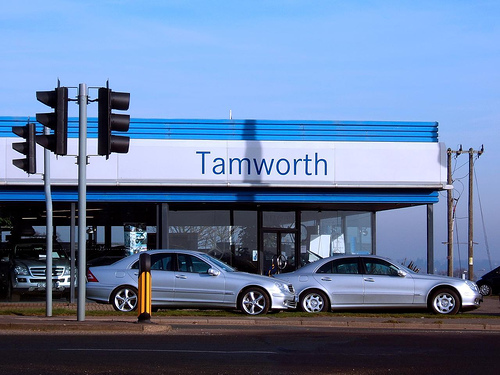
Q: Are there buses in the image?
A: No, there are no buses.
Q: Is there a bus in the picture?
A: No, there are no buses.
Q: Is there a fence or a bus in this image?
A: No, there are no buses or fences.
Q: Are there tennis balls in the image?
A: No, there are no tennis balls.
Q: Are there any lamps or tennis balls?
A: No, there are no tennis balls or lamps.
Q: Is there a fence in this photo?
A: No, there are no fences.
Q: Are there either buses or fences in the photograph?
A: No, there are no fences or buses.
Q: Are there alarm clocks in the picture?
A: No, there are no alarm clocks.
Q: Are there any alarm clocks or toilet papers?
A: No, there are no alarm clocks or toilet papers.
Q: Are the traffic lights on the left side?
A: Yes, the traffic lights are on the left of the image.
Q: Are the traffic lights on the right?
A: No, the traffic lights are on the left of the image.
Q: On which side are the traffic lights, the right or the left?
A: The traffic lights are on the left of the image.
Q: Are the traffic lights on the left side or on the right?
A: The traffic lights are on the left of the image.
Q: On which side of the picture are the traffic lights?
A: The traffic lights are on the left of the image.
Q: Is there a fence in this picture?
A: No, there are no fences.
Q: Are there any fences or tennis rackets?
A: No, there are no fences or tennis rackets.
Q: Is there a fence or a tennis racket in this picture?
A: No, there are no fences or rackets.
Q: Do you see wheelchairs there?
A: No, there are no wheelchairs.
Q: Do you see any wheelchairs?
A: No, there are no wheelchairs.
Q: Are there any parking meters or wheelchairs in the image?
A: No, there are no wheelchairs or parking meters.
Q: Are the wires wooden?
A: Yes, the wires are wooden.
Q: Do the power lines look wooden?
A: Yes, the power lines are wooden.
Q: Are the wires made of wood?
A: Yes, the wires are made of wood.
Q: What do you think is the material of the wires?
A: The wires are made of wood.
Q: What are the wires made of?
A: The wires are made of wood.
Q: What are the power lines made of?
A: The wires are made of wood.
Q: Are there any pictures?
A: No, there are no pictures.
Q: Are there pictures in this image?
A: No, there are no pictures.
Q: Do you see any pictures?
A: No, there are no pictures.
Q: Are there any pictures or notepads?
A: No, there are no pictures or notepads.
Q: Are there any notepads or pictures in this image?
A: No, there are no pictures or notepads.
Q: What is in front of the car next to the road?
A: The street lights are in front of the car.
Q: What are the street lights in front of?
A: The street lights are in front of the car.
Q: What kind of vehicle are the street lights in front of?
A: The street lights are in front of the car.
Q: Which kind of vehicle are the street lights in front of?
A: The street lights are in front of the car.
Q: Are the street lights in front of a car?
A: Yes, the street lights are in front of a car.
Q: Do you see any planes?
A: No, there are no planes.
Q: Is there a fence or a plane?
A: No, there are no airplanes or fences.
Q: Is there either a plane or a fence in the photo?
A: No, there are no airplanes or fences.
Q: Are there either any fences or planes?
A: No, there are no planes or fences.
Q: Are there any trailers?
A: No, there are no trailers.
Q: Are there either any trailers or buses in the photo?
A: No, there are no trailers or buses.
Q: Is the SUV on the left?
A: Yes, the SUV is on the left of the image.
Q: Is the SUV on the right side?
A: No, the SUV is on the left of the image.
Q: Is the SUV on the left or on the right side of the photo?
A: The SUV is on the left of the image.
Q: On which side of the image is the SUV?
A: The SUV is on the left of the image.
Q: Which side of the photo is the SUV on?
A: The SUV is on the left of the image.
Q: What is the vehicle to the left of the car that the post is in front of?
A: The vehicle is a SUV.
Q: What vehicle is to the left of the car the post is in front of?
A: The vehicle is a SUV.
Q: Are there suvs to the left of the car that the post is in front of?
A: Yes, there is a SUV to the left of the car.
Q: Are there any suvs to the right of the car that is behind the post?
A: No, the SUV is to the left of the car.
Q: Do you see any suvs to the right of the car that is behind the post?
A: No, the SUV is to the left of the car.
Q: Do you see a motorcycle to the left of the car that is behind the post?
A: No, there is a SUV to the left of the car.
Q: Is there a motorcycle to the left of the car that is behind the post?
A: No, there is a SUV to the left of the car.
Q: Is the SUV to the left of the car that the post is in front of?
A: Yes, the SUV is to the left of the car.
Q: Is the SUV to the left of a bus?
A: No, the SUV is to the left of the car.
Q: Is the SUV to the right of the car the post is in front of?
A: No, the SUV is to the left of the car.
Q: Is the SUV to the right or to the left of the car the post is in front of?
A: The SUV is to the left of the car.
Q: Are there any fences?
A: No, there are no fences.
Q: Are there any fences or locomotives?
A: No, there are no fences or locomotives.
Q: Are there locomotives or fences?
A: No, there are no fences or locomotives.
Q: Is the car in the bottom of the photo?
A: Yes, the car is in the bottom of the image.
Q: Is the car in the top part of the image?
A: No, the car is in the bottom of the image.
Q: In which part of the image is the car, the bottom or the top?
A: The car is in the bottom of the image.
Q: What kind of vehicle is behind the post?
A: The vehicle is a car.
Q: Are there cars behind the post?
A: Yes, there is a car behind the post.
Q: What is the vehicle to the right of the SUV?
A: The vehicle is a car.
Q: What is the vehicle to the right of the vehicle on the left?
A: The vehicle is a car.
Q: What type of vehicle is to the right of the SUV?
A: The vehicle is a car.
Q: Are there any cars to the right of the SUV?
A: Yes, there is a car to the right of the SUV.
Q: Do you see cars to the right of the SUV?
A: Yes, there is a car to the right of the SUV.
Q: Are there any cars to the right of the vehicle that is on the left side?
A: Yes, there is a car to the right of the SUV.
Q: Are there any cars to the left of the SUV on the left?
A: No, the car is to the right of the SUV.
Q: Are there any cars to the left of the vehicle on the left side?
A: No, the car is to the right of the SUV.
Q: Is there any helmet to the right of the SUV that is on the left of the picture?
A: No, there is a car to the right of the SUV.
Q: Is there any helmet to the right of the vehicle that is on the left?
A: No, there is a car to the right of the SUV.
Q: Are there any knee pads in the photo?
A: No, there are no knee pads.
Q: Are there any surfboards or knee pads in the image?
A: No, there are no knee pads or surfboards.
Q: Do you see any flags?
A: No, there are no flags.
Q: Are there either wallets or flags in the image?
A: No, there are no flags or wallets.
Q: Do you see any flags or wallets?
A: No, there are no flags or wallets.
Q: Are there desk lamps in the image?
A: No, there are no desk lamps.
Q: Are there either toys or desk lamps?
A: No, there are no desk lamps or toys.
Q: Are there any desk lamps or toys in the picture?
A: No, there are no desk lamps or toys.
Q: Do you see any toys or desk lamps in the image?
A: No, there are no desk lamps or toys.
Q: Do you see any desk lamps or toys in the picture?
A: No, there are no desk lamps or toys.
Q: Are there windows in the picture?
A: Yes, there is a window.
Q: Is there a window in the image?
A: Yes, there is a window.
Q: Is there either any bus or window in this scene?
A: Yes, there is a window.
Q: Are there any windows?
A: Yes, there is a window.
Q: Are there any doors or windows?
A: Yes, there is a window.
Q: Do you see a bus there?
A: No, there are no buses.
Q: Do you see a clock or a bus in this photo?
A: No, there are no buses or clocks.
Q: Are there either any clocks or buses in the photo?
A: No, there are no buses or clocks.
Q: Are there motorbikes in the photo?
A: No, there are no motorbikes.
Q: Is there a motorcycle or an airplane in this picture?
A: No, there are no motorcycles or airplanes.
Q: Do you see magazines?
A: No, there are no magazines.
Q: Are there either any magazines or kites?
A: No, there are no magazines or kites.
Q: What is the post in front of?
A: The post is in front of the car.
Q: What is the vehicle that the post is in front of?
A: The vehicle is a car.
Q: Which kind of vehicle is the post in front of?
A: The post is in front of the car.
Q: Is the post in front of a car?
A: Yes, the post is in front of a car.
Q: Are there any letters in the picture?
A: Yes, there are letters.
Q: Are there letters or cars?
A: Yes, there are letters.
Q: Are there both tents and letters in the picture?
A: No, there are letters but no tents.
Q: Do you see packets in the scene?
A: No, there are no packets.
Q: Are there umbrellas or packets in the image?
A: No, there are no packets or umbrellas.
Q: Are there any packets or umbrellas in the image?
A: No, there are no packets or umbrellas.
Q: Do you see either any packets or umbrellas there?
A: No, there are no packets or umbrellas.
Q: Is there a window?
A: Yes, there is a window.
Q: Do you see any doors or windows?
A: Yes, there is a window.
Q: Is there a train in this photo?
A: No, there are no trains.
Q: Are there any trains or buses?
A: No, there are no trains or buses.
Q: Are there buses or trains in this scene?
A: No, there are no trains or buses.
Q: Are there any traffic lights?
A: Yes, there is a traffic light.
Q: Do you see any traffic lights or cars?
A: Yes, there is a traffic light.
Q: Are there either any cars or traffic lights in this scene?
A: Yes, there is a traffic light.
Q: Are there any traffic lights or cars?
A: Yes, there is a traffic light.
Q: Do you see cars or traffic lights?
A: Yes, there is a traffic light.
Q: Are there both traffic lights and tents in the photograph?
A: No, there is a traffic light but no tents.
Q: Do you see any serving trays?
A: No, there are no serving trays.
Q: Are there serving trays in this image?
A: No, there are no serving trays.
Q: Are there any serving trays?
A: No, there are no serving trays.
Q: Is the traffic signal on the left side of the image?
A: Yes, the traffic signal is on the left of the image.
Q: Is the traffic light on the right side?
A: No, the traffic light is on the left of the image.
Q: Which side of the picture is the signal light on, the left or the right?
A: The signal light is on the left of the image.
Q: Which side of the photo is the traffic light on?
A: The traffic light is on the left of the image.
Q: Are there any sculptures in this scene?
A: No, there are no sculptures.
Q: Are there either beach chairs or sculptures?
A: No, there are no sculptures or beach chairs.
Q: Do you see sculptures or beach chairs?
A: No, there are no sculptures or beach chairs.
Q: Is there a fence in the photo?
A: No, there are no fences.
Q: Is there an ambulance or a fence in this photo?
A: No, there are no fences or ambulances.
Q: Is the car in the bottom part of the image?
A: Yes, the car is in the bottom of the image.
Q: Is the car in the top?
A: No, the car is in the bottom of the image.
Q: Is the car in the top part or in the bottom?
A: The car is in the bottom of the image.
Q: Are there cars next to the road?
A: Yes, there is a car next to the road.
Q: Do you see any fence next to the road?
A: No, there is a car next to the road.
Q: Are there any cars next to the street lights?
A: Yes, there is a car next to the street lights.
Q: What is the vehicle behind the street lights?
A: The vehicle is a car.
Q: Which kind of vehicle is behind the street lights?
A: The vehicle is a car.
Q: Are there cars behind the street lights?
A: Yes, there is a car behind the street lights.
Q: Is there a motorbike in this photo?
A: No, there are no motorcycles.